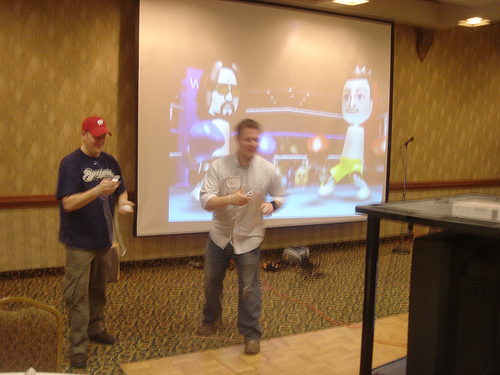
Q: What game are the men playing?
A: Wii.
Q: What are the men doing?
A: Playing a video game.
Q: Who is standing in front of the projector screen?
A: A man.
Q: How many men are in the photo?
A: Two.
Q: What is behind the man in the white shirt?
A: A big tv projector screen.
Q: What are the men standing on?
A: Carpeted floor.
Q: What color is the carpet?
A: Green and brown.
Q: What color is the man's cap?
A: Red.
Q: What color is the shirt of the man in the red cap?
A: Black with white logo.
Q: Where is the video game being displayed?
A: On the projector screen.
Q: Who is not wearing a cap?
A: The man in the white shirt.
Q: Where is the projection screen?
A: On the back wall.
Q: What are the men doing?
A: Playing a video game.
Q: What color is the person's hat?
A: Red.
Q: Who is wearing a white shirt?
A: The man on the right of the picture.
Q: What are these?
A: Man's jeans.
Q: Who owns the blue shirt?
A: The man.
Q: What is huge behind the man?
A: The screen.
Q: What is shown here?
A: The actual TV.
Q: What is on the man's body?
A: Blue jeans.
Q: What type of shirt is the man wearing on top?
A: White button up shirt.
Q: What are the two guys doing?
A: Playing Wii game.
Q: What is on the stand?
A: Television set.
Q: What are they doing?
A: Playing a video game.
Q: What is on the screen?
A: Two boxers.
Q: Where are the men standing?
A: In front of the game console.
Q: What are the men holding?
A: Controllers.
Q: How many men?
A: Two.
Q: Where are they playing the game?
A: In a large room.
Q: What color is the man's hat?
A: Red.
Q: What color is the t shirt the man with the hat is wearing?
A: Blue.